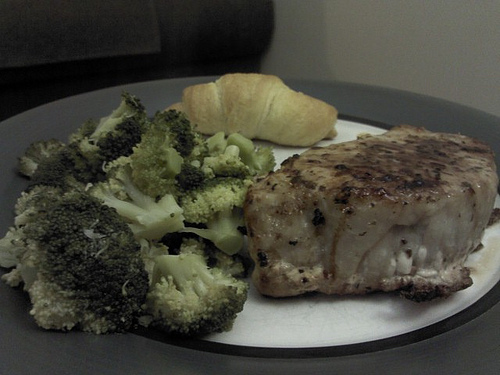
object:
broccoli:
[139, 252, 250, 335]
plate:
[200, 119, 499, 349]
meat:
[252, 124, 500, 304]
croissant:
[171, 71, 332, 144]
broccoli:
[28, 138, 190, 239]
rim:
[355, 91, 417, 115]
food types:
[88, 104, 269, 254]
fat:
[269, 211, 389, 273]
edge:
[247, 196, 295, 297]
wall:
[259, 0, 500, 113]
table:
[0, 71, 500, 375]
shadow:
[288, 52, 323, 78]